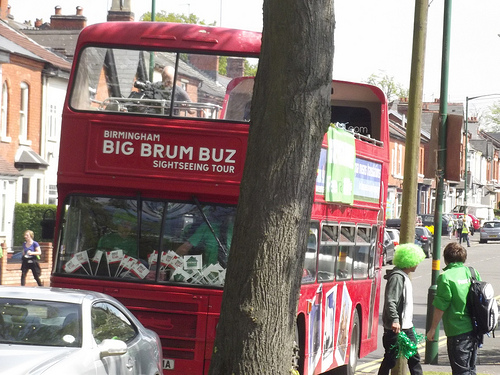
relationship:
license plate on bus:
[150, 352, 174, 370] [69, 97, 334, 363]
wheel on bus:
[339, 305, 358, 370] [69, 97, 334, 363]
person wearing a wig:
[440, 264, 482, 371] [406, 251, 416, 264]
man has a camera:
[149, 68, 183, 102] [123, 80, 151, 99]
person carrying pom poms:
[440, 264, 482, 371] [386, 327, 416, 355]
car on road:
[4, 283, 161, 369] [42, 279, 50, 282]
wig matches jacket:
[389, 241, 424, 269] [456, 288, 466, 329]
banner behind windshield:
[326, 127, 357, 201] [121, 210, 202, 237]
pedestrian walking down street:
[16, 232, 39, 279] [366, 355, 376, 361]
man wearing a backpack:
[149, 68, 183, 102] [472, 280, 488, 329]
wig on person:
[406, 251, 416, 264] [440, 264, 482, 371]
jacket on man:
[456, 288, 466, 329] [149, 68, 183, 102]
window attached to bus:
[193, 60, 246, 121] [69, 97, 334, 363]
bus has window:
[69, 97, 334, 363] [193, 60, 246, 121]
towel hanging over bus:
[314, 123, 350, 145] [69, 97, 334, 363]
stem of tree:
[214, 358, 292, 373] [228, 140, 294, 317]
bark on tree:
[295, 13, 330, 28] [228, 140, 294, 317]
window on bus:
[193, 60, 246, 121] [69, 97, 334, 363]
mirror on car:
[91, 340, 131, 355] [4, 283, 161, 369]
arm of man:
[379, 279, 405, 324] [149, 68, 183, 102]